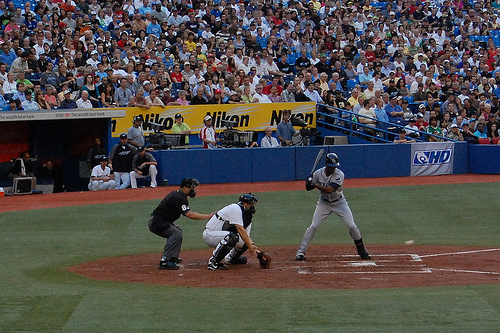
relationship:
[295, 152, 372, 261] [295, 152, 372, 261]
batter baseball players batter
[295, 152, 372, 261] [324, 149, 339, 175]
batter has head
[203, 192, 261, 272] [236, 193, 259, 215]
catcher has head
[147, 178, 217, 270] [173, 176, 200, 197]
human has head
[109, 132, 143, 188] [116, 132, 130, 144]
person has head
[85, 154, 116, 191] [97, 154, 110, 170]
person has head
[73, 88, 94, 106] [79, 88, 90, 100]
person has head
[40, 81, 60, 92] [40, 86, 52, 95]
person has head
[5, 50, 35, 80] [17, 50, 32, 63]
person has head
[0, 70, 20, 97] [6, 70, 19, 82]
person has head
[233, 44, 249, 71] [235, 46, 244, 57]
person has head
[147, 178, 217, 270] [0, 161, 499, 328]
human on baseball field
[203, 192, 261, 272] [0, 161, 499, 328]
catcher on baseball field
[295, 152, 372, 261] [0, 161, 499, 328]
batter on baseball field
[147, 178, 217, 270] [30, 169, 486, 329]
human on field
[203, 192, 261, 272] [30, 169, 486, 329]
catcher on field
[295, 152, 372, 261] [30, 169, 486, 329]
batter on field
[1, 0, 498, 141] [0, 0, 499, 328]
people sitting in baseball field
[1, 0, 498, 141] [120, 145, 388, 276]
people watching baseball game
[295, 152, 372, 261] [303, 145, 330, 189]
batter holding bat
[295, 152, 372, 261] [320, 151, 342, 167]
batter wearing helmet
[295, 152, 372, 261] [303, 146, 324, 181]
batter swinging bat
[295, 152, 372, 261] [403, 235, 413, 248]
batter decides not to swing at ball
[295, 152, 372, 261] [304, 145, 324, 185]
batter holds bat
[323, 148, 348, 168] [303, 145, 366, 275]
helmet worn by human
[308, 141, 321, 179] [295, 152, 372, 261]
bat held by batter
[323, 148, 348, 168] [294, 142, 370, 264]
helmet worn  by human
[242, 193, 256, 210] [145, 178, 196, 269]
mask worn  by human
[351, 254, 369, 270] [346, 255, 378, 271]
dirt on plate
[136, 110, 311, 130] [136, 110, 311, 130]
nikon advertising nikon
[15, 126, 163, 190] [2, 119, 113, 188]
team has dugout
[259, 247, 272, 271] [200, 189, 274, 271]
glove belonging to catcher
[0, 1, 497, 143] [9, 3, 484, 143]
fans in stands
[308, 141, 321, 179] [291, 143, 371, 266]
bat held by batter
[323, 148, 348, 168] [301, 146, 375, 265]
helmet worn by batter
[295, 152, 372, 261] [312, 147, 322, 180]
batter holding bat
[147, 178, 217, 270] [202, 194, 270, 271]
human behind catcher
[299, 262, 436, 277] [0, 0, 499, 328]
lines in baseball field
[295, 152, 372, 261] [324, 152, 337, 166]
batter wearing helmet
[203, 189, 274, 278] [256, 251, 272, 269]
catcher has glove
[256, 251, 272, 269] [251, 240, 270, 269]
glove in hand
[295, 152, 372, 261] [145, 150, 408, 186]
batter standing by wall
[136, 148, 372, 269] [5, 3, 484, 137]
people in bleachers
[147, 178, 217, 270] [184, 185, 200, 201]
human wearing mask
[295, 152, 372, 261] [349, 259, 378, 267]
batter standing by home plate